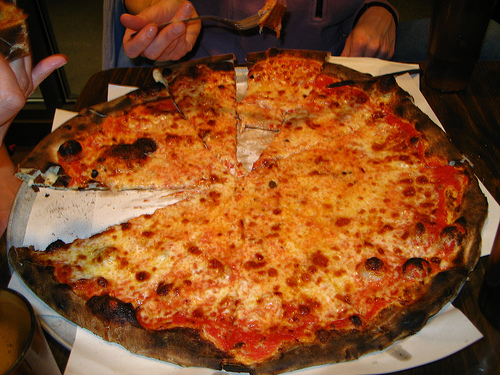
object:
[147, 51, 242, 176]
slice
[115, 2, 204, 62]
hand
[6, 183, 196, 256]
missing slice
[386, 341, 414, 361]
grease stain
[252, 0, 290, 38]
pizza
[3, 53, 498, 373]
cardboard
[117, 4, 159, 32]
fingers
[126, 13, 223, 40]
handle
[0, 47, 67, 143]
hand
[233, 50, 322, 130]
pizza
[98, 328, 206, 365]
edge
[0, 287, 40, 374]
glass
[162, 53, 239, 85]
crust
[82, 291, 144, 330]
spot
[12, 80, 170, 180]
crust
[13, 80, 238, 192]
pizza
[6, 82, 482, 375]
pan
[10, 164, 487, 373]
pizza crust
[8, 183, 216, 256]
pizza cut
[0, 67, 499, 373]
table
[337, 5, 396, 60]
hand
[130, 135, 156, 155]
spot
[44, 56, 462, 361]
cheese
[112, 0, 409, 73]
man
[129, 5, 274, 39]
fork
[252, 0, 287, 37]
food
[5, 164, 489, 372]
cheese pizza